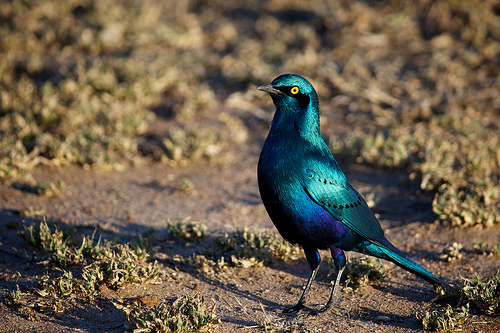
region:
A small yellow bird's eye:
[291, 82, 298, 95]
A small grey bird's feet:
[323, 270, 343, 322]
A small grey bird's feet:
[301, 259, 318, 317]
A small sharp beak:
[248, 84, 274, 92]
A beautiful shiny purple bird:
[243, 68, 413, 331]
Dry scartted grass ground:
[1, 196, 150, 298]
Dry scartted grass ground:
[105, 145, 205, 205]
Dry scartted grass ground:
[426, 140, 476, 255]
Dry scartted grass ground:
[379, 283, 459, 330]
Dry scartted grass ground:
[227, 2, 351, 74]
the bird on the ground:
[235, 68, 398, 318]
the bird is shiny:
[243, 66, 435, 306]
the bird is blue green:
[239, 50, 411, 330]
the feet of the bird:
[258, 265, 360, 319]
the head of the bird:
[237, 58, 334, 136]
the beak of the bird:
[256, 80, 277, 96]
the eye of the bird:
[286, 83, 301, 98]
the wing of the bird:
[293, 154, 404, 264]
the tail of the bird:
[372, 244, 468, 301]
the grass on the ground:
[36, 205, 145, 291]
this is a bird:
[245, 77, 445, 328]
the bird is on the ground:
[248, 78, 439, 321]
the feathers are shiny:
[279, 120, 301, 166]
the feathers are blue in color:
[278, 126, 305, 174]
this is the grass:
[36, 2, 186, 162]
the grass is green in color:
[58, 10, 159, 128]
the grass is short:
[45, 90, 135, 136]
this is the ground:
[89, 172, 146, 224]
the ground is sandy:
[85, 169, 136, 226]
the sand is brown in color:
[113, 170, 144, 221]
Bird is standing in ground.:
[248, 66, 430, 320]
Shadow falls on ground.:
[17, 198, 234, 320]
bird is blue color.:
[253, 70, 423, 287]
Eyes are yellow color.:
[283, 80, 310, 107]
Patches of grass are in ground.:
[31, 57, 178, 309]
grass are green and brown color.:
[16, 83, 174, 306]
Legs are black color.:
[244, 247, 347, 332]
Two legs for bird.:
[249, 260, 368, 332]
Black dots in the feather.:
[285, 157, 379, 234]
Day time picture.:
[58, 23, 464, 317]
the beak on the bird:
[258, 82, 276, 97]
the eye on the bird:
[291, 84, 299, 94]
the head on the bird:
[257, 70, 318, 113]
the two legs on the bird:
[287, 246, 349, 319]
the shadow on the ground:
[8, 195, 270, 321]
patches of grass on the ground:
[10, 4, 498, 228]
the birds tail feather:
[361, 235, 463, 300]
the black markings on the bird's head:
[277, 81, 309, 106]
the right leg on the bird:
[283, 249, 320, 322]